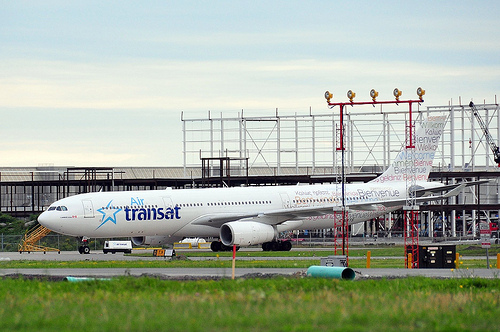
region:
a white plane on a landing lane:
[28, 98, 473, 263]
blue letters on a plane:
[86, 188, 191, 240]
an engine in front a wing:
[213, 214, 285, 250]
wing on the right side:
[272, 169, 472, 239]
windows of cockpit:
[39, 187, 78, 224]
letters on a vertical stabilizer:
[373, 95, 457, 178]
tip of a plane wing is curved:
[388, 160, 478, 212]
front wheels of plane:
[65, 235, 99, 265]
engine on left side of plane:
[127, 228, 180, 254]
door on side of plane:
[76, 192, 102, 225]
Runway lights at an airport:
[319, 83, 437, 106]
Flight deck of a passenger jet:
[42, 196, 75, 213]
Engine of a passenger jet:
[212, 218, 289, 248]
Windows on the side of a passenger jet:
[206, 198, 273, 206]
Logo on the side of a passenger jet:
[100, 195, 187, 225]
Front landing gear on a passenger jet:
[75, 232, 91, 257]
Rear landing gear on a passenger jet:
[262, 233, 287, 254]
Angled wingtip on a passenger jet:
[438, 178, 472, 202]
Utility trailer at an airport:
[98, 234, 142, 256]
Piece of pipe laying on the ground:
[307, 256, 359, 288]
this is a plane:
[43, 153, 375, 243]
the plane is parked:
[38, 164, 384, 255]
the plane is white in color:
[204, 185, 237, 212]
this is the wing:
[292, 186, 371, 227]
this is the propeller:
[218, 215, 274, 250]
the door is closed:
[80, 195, 95, 217]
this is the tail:
[411, 110, 446, 158]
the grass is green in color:
[254, 280, 347, 330]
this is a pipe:
[306, 258, 355, 288]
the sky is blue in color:
[174, 22, 249, 69]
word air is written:
[125, 193, 140, 206]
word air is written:
[131, 190, 143, 208]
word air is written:
[129, 194, 144, 216]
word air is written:
[133, 193, 138, 214]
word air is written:
[130, 197, 136, 202]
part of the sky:
[84, 3, 129, 48]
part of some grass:
[251, 289, 277, 308]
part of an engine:
[243, 222, 265, 242]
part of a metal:
[311, 219, 357, 224]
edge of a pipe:
[310, 257, 333, 279]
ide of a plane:
[112, 185, 174, 252]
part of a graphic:
[140, 206, 173, 234]